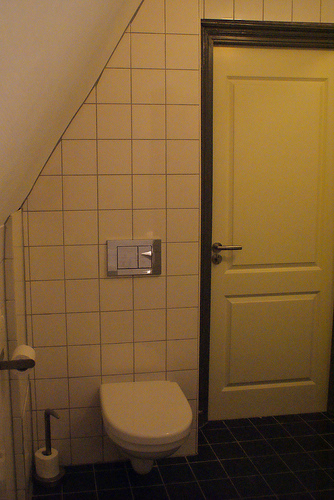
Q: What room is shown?
A: Bathroom.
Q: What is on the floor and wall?
A: Tiles.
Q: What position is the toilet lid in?
A: Down.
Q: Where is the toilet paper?
A: Left side of the toilet.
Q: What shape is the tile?
A: Square.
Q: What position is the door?
A: Closed.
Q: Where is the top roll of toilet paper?
A: Hanging on the wall.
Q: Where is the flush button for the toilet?
A: On the wall behind the toilet.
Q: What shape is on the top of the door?
A: Rectangle.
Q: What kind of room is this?
A: Bathroom.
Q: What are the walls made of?
A: Tiles.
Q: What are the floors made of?
A: Black tiles.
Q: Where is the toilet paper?
A: On the left wall.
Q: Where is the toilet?
A: To the left of the door.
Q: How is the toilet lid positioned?
A: Closed and down.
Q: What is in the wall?
A: Toilet paper.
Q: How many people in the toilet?
A: Zero.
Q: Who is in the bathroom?
A: No one.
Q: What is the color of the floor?
A: Black.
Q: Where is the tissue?
A: On the wall.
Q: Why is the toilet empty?
A: No one is using it.